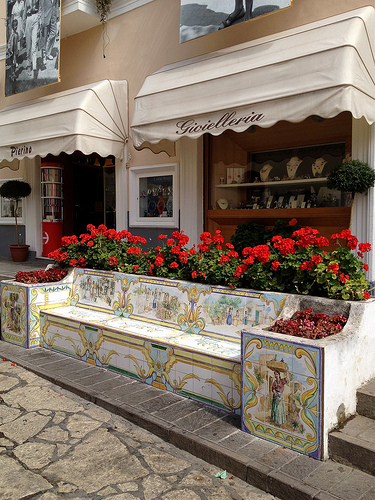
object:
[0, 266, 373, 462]
bench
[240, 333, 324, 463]
painting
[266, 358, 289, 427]
woman with basket on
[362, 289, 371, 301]
flowers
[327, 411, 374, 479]
steps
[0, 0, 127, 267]
shops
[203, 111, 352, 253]
window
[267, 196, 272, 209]
watches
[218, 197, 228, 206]
jewelry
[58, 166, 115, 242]
entryway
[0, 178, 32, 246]
tree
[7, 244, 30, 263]
pot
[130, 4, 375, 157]
awning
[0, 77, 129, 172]
awning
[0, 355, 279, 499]
street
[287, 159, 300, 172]
necklace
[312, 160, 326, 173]
necklace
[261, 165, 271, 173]
necklace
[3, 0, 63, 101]
artwork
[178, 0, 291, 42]
artwork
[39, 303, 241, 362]
seat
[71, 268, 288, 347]
back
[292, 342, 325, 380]
tiles